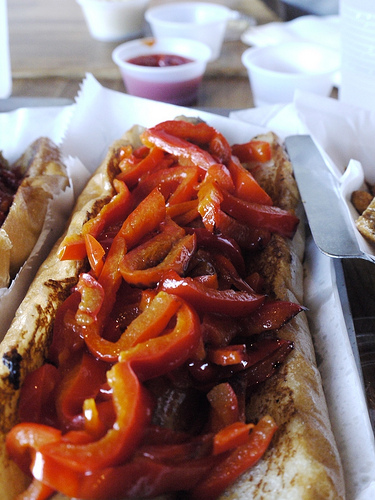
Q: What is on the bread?
A: Peppers.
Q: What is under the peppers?
A: Bread.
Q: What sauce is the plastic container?
A: Ketchup.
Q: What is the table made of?
A: Wood.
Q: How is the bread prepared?
A: Toasted.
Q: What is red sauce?
A: Ketchup.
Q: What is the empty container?
A: Plastic.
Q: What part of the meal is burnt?
A: The bread.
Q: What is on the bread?
A: Peppers.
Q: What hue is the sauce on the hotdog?
A: Red.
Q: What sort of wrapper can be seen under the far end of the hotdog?
A: White paper wrapper.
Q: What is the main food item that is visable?
A: A sausage sandwitch.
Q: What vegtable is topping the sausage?
A: Peppers.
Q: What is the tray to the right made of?
A: Metal.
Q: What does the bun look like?
A: Long and toasted.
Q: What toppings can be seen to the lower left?
A: Red pepper slices.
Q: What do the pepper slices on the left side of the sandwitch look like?
A: Thin, long and red.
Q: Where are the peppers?
A: On top of the sausage.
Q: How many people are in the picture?
A: None.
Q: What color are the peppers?
A: Red.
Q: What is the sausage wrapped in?
A: Bun.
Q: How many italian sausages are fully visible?
A: One.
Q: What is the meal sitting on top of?
A: Table.